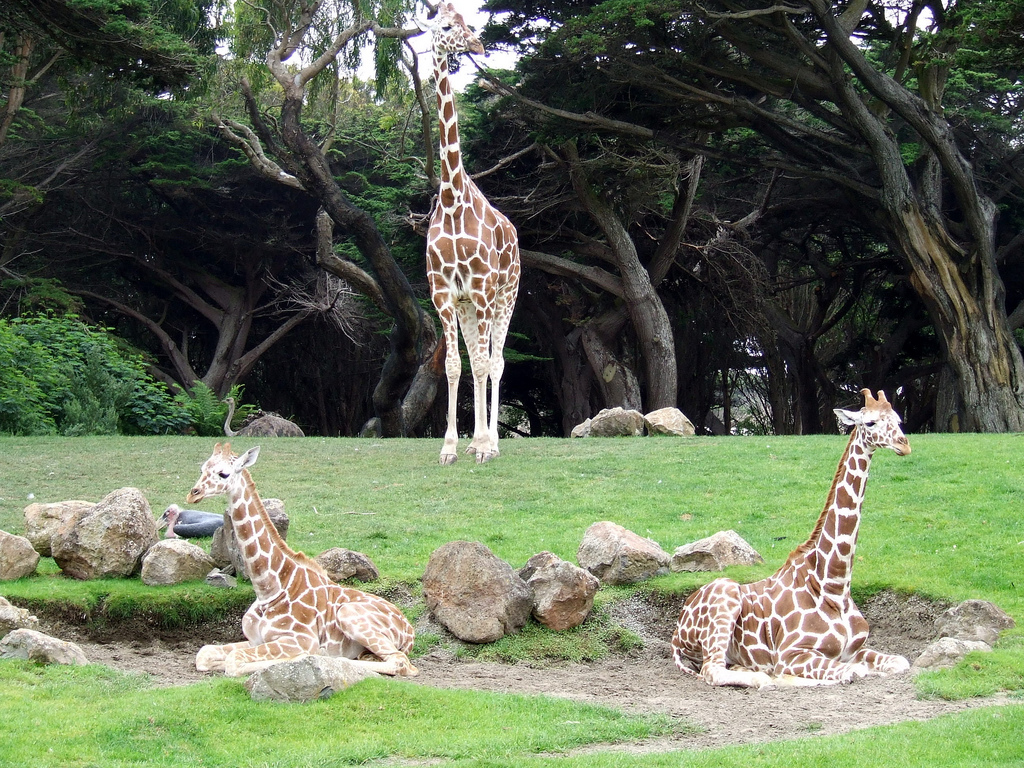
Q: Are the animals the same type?
A: Yes, all the animals are giraffes.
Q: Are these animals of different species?
A: No, all the animals are giraffes.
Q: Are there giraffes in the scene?
A: Yes, there is a giraffe.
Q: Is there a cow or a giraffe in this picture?
A: Yes, there is a giraffe.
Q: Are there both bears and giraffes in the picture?
A: No, there is a giraffe but no bears.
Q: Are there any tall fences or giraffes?
A: Yes, there is a tall giraffe.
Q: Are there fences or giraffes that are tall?
A: Yes, the giraffe is tall.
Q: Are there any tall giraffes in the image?
A: Yes, there is a tall giraffe.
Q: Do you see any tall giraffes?
A: Yes, there is a tall giraffe.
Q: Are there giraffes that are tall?
A: Yes, there is a giraffe that is tall.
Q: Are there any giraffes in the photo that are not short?
A: Yes, there is a tall giraffe.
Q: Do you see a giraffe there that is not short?
A: Yes, there is a tall giraffe.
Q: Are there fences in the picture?
A: No, there are no fences.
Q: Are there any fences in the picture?
A: No, there are no fences.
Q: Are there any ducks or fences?
A: No, there are no fences or ducks.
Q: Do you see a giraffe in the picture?
A: Yes, there is a giraffe.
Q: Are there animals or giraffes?
A: Yes, there is a giraffe.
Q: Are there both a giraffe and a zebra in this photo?
A: No, there is a giraffe but no zebras.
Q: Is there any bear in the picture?
A: No, there are no bears.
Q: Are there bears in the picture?
A: No, there are no bears.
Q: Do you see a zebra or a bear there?
A: No, there are no bears or zebras.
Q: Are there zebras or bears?
A: No, there are no bears or zebras.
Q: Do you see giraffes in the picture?
A: Yes, there is a giraffe.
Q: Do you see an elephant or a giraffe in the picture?
A: Yes, there is a giraffe.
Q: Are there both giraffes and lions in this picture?
A: No, there is a giraffe but no lions.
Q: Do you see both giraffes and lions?
A: No, there is a giraffe but no lions.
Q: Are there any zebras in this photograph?
A: No, there are no zebras.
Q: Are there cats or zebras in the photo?
A: No, there are no zebras or cats.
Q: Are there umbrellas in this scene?
A: No, there are no umbrellas.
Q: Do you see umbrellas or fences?
A: No, there are no umbrellas or fences.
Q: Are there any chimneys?
A: No, there are no chimneys.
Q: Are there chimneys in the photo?
A: No, there are no chimneys.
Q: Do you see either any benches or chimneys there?
A: No, there are no chimneys or benches.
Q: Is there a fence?
A: No, there are no fences.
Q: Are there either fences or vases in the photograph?
A: No, there are no fences or vases.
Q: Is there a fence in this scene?
A: No, there are no fences.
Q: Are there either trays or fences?
A: No, there are no fences or trays.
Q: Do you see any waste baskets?
A: No, there are no waste baskets.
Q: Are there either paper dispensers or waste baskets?
A: No, there are no waste baskets or paper dispensers.